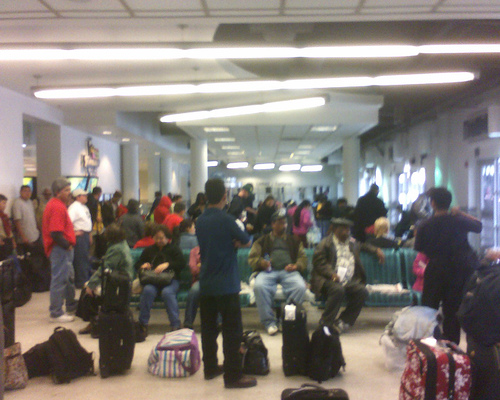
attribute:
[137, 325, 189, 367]
duffle bag — striped, purple, yellow, blue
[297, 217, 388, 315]
jacket — brown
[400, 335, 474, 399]
suitcase — red, white, floral print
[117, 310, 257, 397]
backpack — black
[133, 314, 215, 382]
rainbow bag — rainbow colored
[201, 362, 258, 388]
shoes — brown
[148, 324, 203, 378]
bag — striped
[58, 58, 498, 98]
light — bright, white, fluorescent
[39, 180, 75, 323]
man — standing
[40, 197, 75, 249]
shirt — red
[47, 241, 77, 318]
jeans — blue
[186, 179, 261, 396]
man — standing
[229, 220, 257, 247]
arms — crossed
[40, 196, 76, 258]
shirt — red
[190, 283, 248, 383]
pants — black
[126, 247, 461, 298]
bench — long, padded, teal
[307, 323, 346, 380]
suitcase — black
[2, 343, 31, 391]
bag — cheetah print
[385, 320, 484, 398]
suitcase — black , red 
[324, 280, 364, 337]
trousers — brown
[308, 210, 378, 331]
man — black, sitting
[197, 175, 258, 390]
man — standing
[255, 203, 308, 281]
man — African American, sitting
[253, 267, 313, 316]
jeans — blue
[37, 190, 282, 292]
people — standing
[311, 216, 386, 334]
man — sitting, black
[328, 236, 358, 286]
shirt — white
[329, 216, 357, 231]
hat — black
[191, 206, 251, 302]
shirt — blue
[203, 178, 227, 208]
hair — black